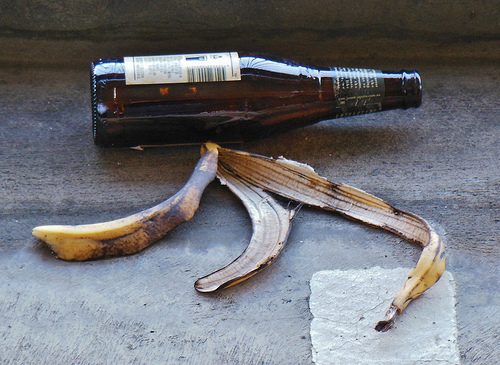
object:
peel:
[32, 139, 447, 332]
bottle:
[90, 51, 423, 148]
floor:
[1, 1, 499, 365]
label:
[124, 52, 243, 86]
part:
[187, 168, 217, 194]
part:
[32, 216, 141, 239]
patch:
[308, 265, 461, 364]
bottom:
[89, 61, 99, 145]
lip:
[413, 70, 423, 110]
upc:
[186, 63, 227, 83]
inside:
[197, 148, 430, 292]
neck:
[319, 65, 403, 121]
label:
[330, 65, 387, 118]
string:
[285, 199, 294, 209]